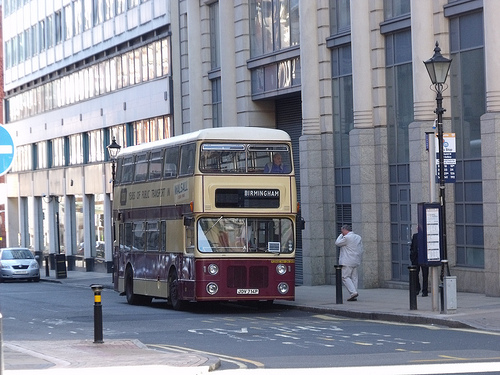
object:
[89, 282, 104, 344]
pole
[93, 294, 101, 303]
yellow sticker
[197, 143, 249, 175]
windows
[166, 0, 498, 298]
building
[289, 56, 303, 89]
window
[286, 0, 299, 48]
window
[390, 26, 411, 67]
window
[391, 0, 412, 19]
window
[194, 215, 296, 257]
windows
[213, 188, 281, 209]
black rectangle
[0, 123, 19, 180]
sign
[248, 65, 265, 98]
window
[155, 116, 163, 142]
windows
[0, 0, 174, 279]
building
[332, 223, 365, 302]
man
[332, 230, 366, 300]
white suit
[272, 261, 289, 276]
headlamp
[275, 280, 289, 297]
headlamp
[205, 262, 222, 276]
headlamp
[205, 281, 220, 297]
headlamp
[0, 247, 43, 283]
car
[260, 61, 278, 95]
window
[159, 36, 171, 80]
window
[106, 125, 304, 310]
bus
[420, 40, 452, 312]
lamp post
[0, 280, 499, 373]
street